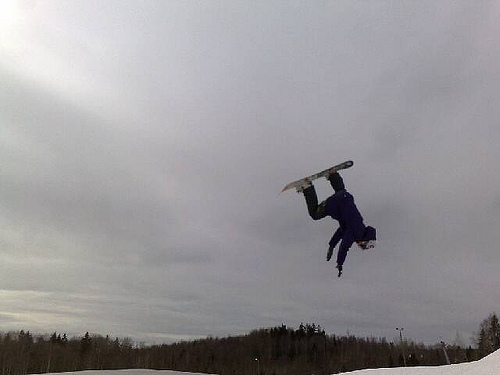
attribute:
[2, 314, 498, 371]
trees — tallest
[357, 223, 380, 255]
head — tilted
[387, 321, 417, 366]
pole — tall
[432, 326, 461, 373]
pole — short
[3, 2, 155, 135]
light — muted rays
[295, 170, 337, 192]
feet — under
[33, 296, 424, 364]
hills — distant